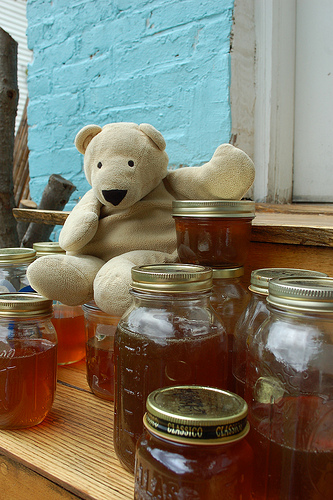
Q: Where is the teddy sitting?
A: On a jar of honey.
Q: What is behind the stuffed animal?
A: Blue brick wall.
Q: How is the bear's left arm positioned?
A: Resting on top of a jar.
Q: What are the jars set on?
A: A wooden table top.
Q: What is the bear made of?
A: Stuffed fabric.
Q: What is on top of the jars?
A: A teddy bear.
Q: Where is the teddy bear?
A: On top of the jars.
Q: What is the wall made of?
A: Bricks.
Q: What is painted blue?
A: The wall.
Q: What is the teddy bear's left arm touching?
A: The jar.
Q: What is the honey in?
A: Jars.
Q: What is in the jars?
A: Honey.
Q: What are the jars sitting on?
A: Wood.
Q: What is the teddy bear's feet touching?
A: Jars.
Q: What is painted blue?
A: Side of a building.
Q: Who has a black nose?
A: Teddy bear.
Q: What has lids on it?
A: Many jars.